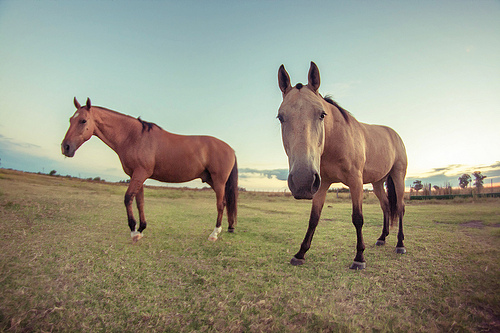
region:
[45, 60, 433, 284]
Two brown colored horses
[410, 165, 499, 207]
A group of trees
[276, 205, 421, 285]
Four dark brown horse legs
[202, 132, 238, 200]
Hind quarter of a brown horse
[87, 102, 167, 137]
Dark colored horse mane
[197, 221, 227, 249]
White horse hoof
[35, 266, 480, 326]
Green and brown grass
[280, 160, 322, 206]
Large horse nostrils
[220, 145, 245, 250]
Long brown horse tail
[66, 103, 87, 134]
White blaze on horses head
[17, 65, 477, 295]
Two horses in a field.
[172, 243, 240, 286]
The grass is green.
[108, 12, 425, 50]
The sky is light blue.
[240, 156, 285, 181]
Clouds in the sky.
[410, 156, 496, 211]
Trees in the distance.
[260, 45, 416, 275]
The horse is light brown.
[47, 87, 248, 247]
The horse is chocolate brown.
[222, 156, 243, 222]
The horse tail is brown.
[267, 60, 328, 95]
The horse has two ears.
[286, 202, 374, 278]
The horse has two front legs.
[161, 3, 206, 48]
part of the sky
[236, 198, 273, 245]
part of a field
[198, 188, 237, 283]
part of a field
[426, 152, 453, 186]
part of a cloud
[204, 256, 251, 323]
part of a field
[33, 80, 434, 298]
two horses in the field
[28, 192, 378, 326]
the field of grass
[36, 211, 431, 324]
the grass is green and trimmed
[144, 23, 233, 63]
the clear blue sky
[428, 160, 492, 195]
the sun is setting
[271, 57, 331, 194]
the head of the horse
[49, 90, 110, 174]
the head of the horse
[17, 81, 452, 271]
two horses standing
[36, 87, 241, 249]
the horse is brown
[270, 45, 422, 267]
the horse is lighter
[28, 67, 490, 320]
Two horses in a field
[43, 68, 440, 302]
The horses are not grazing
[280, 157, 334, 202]
A large brown nose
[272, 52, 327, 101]
The horse has two ears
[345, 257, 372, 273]
Small grey hoof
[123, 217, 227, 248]
Four small white hooves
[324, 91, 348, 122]
A black horse mane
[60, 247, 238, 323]
Short grass beneath the horses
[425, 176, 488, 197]
Trees in the distance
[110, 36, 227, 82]
An open blue sky